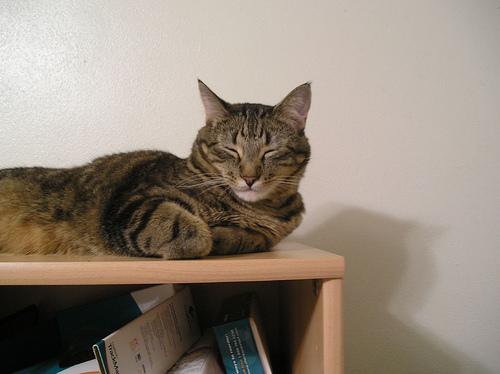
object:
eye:
[223, 144, 243, 161]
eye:
[261, 147, 277, 160]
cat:
[0, 76, 312, 260]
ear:
[271, 82, 313, 130]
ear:
[197, 77, 233, 124]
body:
[0, 149, 306, 259]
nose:
[238, 173, 261, 187]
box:
[211, 289, 276, 374]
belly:
[12, 216, 101, 254]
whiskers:
[166, 170, 236, 201]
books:
[92, 285, 203, 374]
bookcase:
[0, 239, 347, 373]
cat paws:
[165, 246, 211, 260]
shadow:
[288, 203, 492, 373]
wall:
[0, 0, 499, 372]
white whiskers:
[267, 173, 308, 194]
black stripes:
[112, 79, 319, 254]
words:
[221, 324, 255, 373]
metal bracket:
[312, 278, 321, 297]